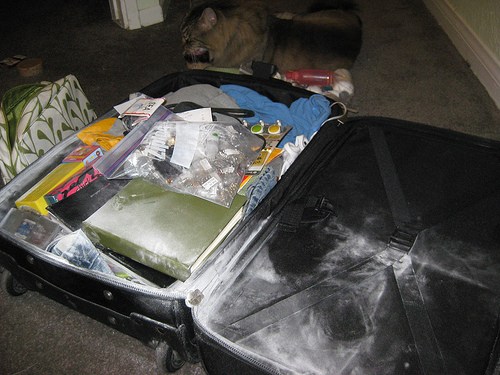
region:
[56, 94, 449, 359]
A suitcase on the ground.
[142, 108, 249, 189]
Ziploc plastic bag in the suitcase.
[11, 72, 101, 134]
A green and white bag on the floor.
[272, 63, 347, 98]
A pink bottle on the floor.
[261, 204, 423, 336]
White powder in the suitcase.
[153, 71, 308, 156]
Clothes in the suitcase.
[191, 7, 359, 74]
A dog on the floor.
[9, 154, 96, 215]
A yellow box in the suitcase.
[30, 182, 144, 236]
A black notebook in the suitcase.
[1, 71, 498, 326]
an open suitcase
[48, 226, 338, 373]
it appears something white & powdery has spilled inside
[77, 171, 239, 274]
a book with a green cover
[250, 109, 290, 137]
a case for contact lenses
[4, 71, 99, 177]
this is a green & white package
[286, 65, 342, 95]
a red bottle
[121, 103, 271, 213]
a plastic ziplock bag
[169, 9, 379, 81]
an animal is next to the suitcase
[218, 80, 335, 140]
a blue piece of clothing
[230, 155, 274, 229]
the hem of a pair of jeans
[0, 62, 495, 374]
an open black suitcase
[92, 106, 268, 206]
a Ziploc bag in the suitcase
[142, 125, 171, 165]
the brand Ziploc on the bag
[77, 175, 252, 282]
a dark green book in the suitcase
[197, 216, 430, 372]
white powder on the suitcase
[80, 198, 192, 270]
white powder on the book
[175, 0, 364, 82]
a cat lounging on the floor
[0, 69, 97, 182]
a small green and white bag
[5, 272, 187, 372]
rolling wheels on the bottom of the suitcase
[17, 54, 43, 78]
a small bowl on the floor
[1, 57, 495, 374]
the suitcase is empty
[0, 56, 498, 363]
the suitcase is open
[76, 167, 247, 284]
the cover of book is green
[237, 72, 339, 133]
a blue cloth in the suitcase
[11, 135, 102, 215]
the box is yellow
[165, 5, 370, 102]
a dog lying on side the suitcase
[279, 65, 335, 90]
a pink bottle next a suitcase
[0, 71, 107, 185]
the bag is white and green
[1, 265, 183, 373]
wheels of suitcase are black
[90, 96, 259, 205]
a plastic bag in suitcase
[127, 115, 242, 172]
item inside the suitcase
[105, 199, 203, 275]
item inside the suitcase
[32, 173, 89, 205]
item inside the suitcase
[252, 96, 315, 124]
item inside the suitcase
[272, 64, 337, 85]
item inside the suitcase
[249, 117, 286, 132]
item inside the suitcase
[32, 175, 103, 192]
item inside the suitcase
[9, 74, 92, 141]
item inside the suitcase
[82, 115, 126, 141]
item inside the suitcase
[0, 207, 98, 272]
item inside the suitcase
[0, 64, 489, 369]
An open suitcase containing many things.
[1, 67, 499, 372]
black suitcase is open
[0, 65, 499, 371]
black suitcase is covered in white powder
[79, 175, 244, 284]
green book is inside suitcase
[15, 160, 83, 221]
yellow box is inside suitcase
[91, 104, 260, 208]
plastic bag sits inside suitcase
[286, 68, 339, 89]
bottle is behind black suitcase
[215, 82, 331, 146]
blue garment rests inside suitcase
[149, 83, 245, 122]
grey garment rests in suitcase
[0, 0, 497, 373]
floor is covered in grey carpet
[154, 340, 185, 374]
wheel belongs to suitcase